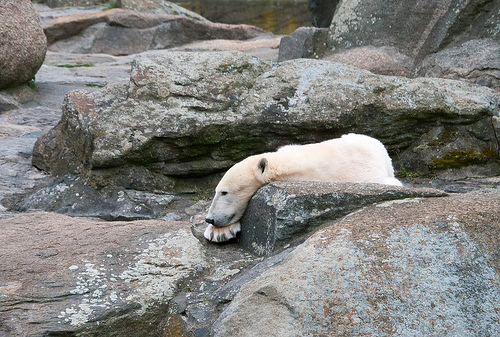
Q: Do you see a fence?
A: No, there are no fences.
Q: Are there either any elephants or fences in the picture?
A: No, there are no fences or elephants.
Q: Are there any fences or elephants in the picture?
A: No, there are no fences or elephants.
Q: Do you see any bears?
A: Yes, there is a bear.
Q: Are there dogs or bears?
A: Yes, there is a bear.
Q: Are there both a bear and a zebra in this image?
A: No, there is a bear but no zebras.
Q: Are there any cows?
A: No, there are no cows.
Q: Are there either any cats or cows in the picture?
A: No, there are no cows or cats.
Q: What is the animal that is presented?
A: The animal is a bear.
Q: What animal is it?
A: The animal is a bear.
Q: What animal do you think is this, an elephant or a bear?
A: This is a bear.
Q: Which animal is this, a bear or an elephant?
A: This is a bear.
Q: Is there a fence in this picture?
A: No, there are no fences.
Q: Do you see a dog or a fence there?
A: No, there are no fences or dogs.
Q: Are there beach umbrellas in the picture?
A: No, there are no beach umbrellas.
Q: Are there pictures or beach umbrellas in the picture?
A: No, there are no beach umbrellas or pictures.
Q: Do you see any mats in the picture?
A: No, there are no mats.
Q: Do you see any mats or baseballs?
A: No, there are no mats or baseballs.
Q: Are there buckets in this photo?
A: No, there are no buckets.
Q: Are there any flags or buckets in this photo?
A: No, there are no buckets or flags.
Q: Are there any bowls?
A: No, there are no bowls.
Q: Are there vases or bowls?
A: No, there are no bowls or vases.